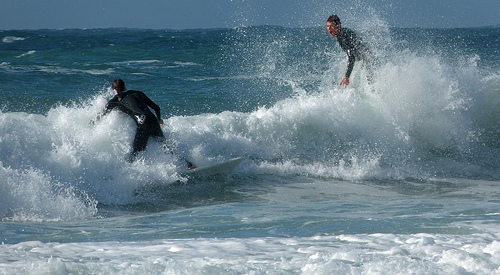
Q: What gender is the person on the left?
A: Male.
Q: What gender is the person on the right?
A: Right.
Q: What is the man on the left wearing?
A: Wetsuit.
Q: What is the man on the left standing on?
A: Surfboard.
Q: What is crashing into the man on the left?
A: Wave.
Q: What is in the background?
A: Water.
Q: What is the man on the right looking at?
A: The man on the left.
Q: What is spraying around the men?
A: Water.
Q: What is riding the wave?
A: The surfers.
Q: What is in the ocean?
A: Two people.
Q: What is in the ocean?
A: The person.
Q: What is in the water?
A: The white wave.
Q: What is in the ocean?
A: The surfer.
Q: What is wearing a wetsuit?
A: The man.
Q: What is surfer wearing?
A: Wetsuit.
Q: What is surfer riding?
A: Wave.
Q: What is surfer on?
A: Surfboard.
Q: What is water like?
A: Rough.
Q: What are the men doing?
A: Surfing.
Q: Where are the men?
A: In the ocean.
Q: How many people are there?
A: Two.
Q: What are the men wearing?
A: Wetsuits.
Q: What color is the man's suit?
A: Black.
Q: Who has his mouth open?
A: The man on the right.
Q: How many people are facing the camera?
A: One.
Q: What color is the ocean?
A: Blue.